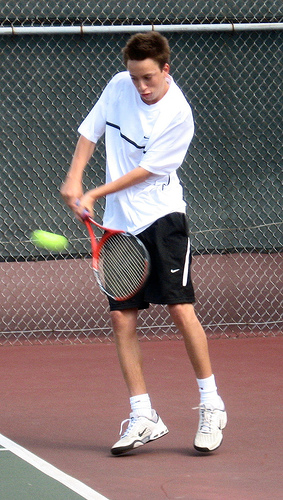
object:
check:
[135, 425, 150, 435]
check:
[166, 264, 182, 276]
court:
[1, 0, 280, 499]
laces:
[114, 411, 142, 440]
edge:
[111, 436, 147, 454]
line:
[180, 232, 194, 290]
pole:
[0, 20, 281, 41]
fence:
[0, 2, 281, 344]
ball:
[27, 228, 67, 258]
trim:
[190, 437, 227, 456]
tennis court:
[5, 343, 266, 498]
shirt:
[82, 74, 190, 244]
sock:
[128, 392, 155, 419]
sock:
[195, 373, 224, 407]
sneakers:
[193, 396, 226, 451]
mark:
[133, 426, 148, 437]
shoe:
[109, 408, 169, 456]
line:
[0, 434, 106, 498]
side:
[110, 416, 172, 447]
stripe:
[104, 110, 175, 170]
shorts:
[102, 211, 196, 311]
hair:
[124, 30, 172, 71]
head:
[126, 32, 169, 101]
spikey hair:
[123, 28, 169, 66]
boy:
[60, 31, 228, 456]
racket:
[69, 203, 149, 305]